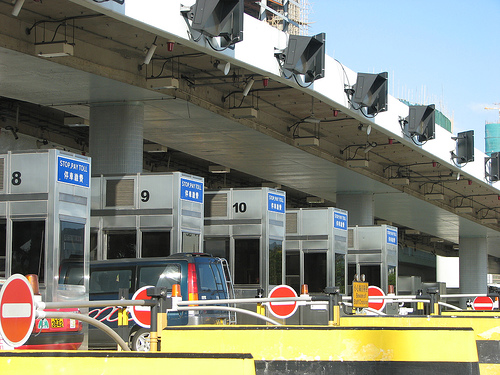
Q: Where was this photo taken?
A: At a toll booth.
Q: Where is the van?
A: In lane 8.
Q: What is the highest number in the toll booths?
A: 10.